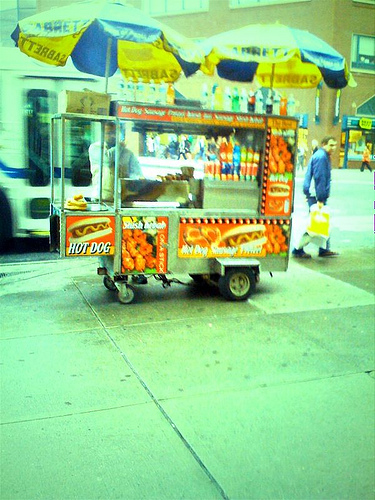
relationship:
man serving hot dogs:
[88, 121, 150, 283] [117, 179, 165, 206]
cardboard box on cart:
[56, 90, 109, 116] [47, 99, 301, 304]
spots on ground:
[21, 283, 369, 410] [0, 167, 374, 499]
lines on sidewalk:
[2, 263, 373, 499] [0, 245, 374, 499]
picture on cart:
[65, 126, 295, 277] [47, 99, 301, 304]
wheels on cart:
[186, 264, 255, 299] [47, 99, 301, 304]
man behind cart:
[88, 121, 150, 283] [47, 99, 301, 304]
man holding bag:
[293, 138, 340, 261] [304, 203, 331, 244]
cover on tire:
[214, 258, 262, 276] [221, 267, 255, 300]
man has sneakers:
[293, 138, 340, 261] [292, 245, 340, 258]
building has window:
[2, 0, 374, 171] [344, 128, 374, 164]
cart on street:
[47, 99, 301, 304] [0, 168, 374, 266]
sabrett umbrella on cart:
[10, 1, 205, 86] [47, 99, 301, 304]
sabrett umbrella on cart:
[198, 19, 357, 87] [47, 99, 301, 304]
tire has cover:
[221, 267, 255, 300] [214, 258, 262, 276]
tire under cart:
[221, 267, 255, 300] [47, 99, 301, 304]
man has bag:
[293, 138, 340, 261] [304, 203, 331, 244]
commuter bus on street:
[0, 45, 170, 244] [0, 168, 374, 266]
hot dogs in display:
[117, 179, 165, 206] [52, 110, 264, 216]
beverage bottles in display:
[202, 140, 260, 182] [52, 110, 264, 216]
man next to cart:
[293, 138, 340, 261] [47, 99, 301, 304]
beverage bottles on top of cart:
[118, 75, 297, 115] [47, 99, 301, 304]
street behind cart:
[0, 168, 374, 266] [47, 99, 301, 304]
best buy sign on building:
[359, 117, 372, 129] [2, 0, 374, 171]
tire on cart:
[221, 267, 255, 300] [47, 99, 301, 304]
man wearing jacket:
[293, 138, 340, 261] [302, 149, 331, 199]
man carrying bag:
[293, 138, 340, 261] [304, 203, 331, 244]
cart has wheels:
[47, 99, 301, 304] [186, 264, 255, 299]